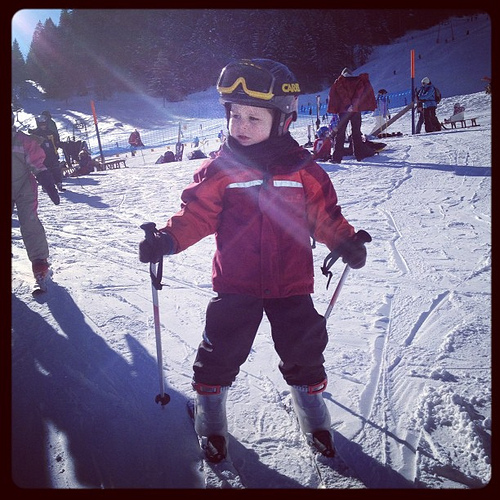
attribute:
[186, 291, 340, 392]
pants — grey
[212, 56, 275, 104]
eyewear — yellow , black , protective 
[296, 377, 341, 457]
boot — grey 